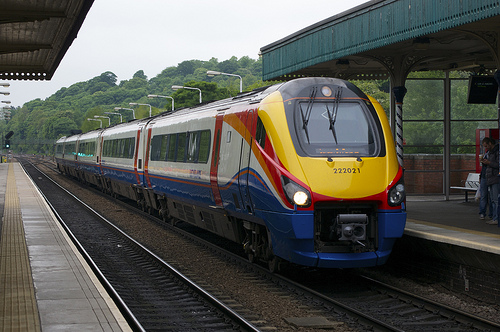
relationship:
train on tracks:
[144, 63, 423, 272] [183, 278, 409, 320]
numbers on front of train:
[332, 164, 364, 178] [144, 63, 423, 272]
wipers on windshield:
[297, 87, 345, 145] [289, 85, 376, 156]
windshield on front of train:
[289, 85, 376, 156] [144, 63, 423, 272]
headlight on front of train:
[287, 183, 313, 208] [144, 63, 423, 272]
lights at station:
[113, 68, 222, 97] [56, 9, 471, 235]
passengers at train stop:
[466, 130, 498, 228] [389, 23, 472, 243]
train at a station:
[144, 63, 423, 272] [56, 9, 471, 235]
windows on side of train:
[149, 131, 210, 162] [144, 63, 423, 272]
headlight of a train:
[287, 183, 313, 208] [144, 63, 423, 272]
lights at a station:
[113, 68, 222, 97] [56, 9, 471, 235]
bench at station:
[454, 170, 475, 194] [56, 9, 471, 235]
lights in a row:
[113, 68, 222, 97] [144, 85, 192, 98]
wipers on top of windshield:
[297, 87, 345, 145] [289, 85, 376, 156]